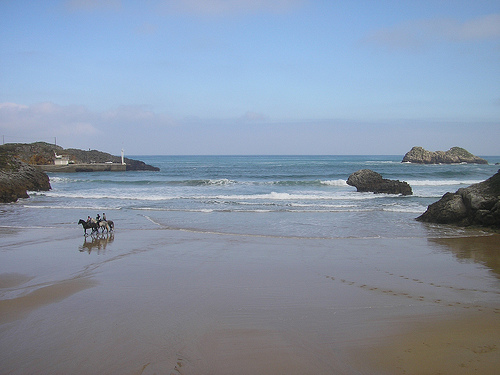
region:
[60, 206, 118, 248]
people horseback riding on a beach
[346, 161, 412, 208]
a large black rock on the shore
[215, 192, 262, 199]
white foam on the waves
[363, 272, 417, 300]
wet tracks in the sand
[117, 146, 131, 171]
a tall white pole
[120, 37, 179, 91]
a clear blue sky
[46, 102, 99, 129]
clouds hanging low in the sky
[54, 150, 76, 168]
a white beach house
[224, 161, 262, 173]
a blue ocean with waves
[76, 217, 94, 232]
a black horse on the beach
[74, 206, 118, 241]
these are horses walking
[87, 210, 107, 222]
these are people on the horses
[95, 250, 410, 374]
the sand is wet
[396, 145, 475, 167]
this is a rock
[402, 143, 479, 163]
the rock is big in size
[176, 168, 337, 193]
the waves are heavy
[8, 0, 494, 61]
the sky is blue in color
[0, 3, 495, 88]
the sky is clear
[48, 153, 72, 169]
this is a tower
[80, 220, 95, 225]
the horse is black in coor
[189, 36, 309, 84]
the sky is blue in color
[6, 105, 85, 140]
the sky has clouds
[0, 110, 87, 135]
the clouds are white in color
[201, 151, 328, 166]
this is the ocean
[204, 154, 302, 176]
the ocean is blue in color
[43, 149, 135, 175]
this is a building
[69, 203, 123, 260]
this are people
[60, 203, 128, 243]
this people are ridding horses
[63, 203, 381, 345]
this is off shore sand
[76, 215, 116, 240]
Three horses on a beach.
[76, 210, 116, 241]
People riding horses.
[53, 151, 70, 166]
a house on the beach.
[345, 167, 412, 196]
A big gray boulder.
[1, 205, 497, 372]
A brown sandy beach.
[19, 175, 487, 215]
Wave in the ocean.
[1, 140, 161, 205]
Mountains in the background.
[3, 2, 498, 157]
a cloudy blue sky.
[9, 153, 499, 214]
The big blue ocean.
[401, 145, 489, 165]
A small rock island.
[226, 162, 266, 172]
section of an ocean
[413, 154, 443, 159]
section of a rock in the ocean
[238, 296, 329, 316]
section of an ocean shore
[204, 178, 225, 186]
the waves of an ocean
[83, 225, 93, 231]
a horse on the oceans shore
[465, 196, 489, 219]
a rock on the ocean shore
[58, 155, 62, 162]
section of a house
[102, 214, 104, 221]
a person on a horse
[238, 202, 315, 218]
ripples of water from the ocean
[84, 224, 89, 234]
section of a black horse